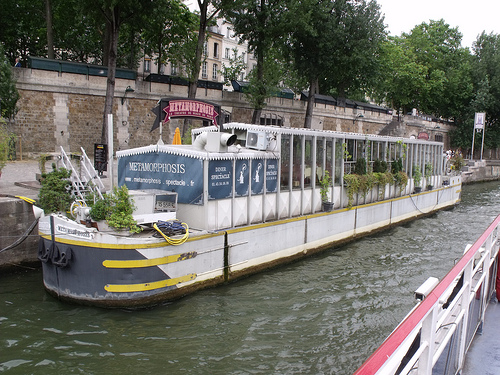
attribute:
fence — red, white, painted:
[358, 214, 497, 375]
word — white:
[129, 162, 184, 174]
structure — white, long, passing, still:
[38, 121, 462, 309]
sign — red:
[164, 98, 221, 126]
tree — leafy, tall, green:
[55, 0, 197, 145]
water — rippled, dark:
[0, 178, 498, 374]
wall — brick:
[3, 65, 499, 158]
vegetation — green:
[94, 187, 145, 234]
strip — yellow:
[38, 231, 156, 251]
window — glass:
[280, 133, 293, 190]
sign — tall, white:
[472, 113, 486, 160]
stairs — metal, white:
[59, 144, 106, 204]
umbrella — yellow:
[173, 129, 181, 143]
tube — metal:
[194, 131, 236, 151]